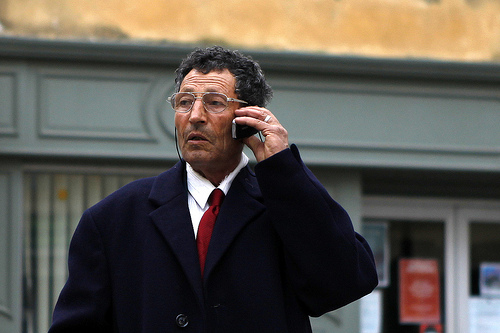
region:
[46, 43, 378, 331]
Man talking on his cell phone.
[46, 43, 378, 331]
Man wearing a dark red tie.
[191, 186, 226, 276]
Dark red tie.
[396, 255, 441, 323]
Red sign on a glass door.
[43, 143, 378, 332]
Navy blue wool coat.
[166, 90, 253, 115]
Eye glasses.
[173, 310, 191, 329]
Top button for a wool coat.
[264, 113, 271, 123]
Ring on man's finger.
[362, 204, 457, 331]
Glass door with signs on it.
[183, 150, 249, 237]
White dress shirt.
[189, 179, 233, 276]
Very bright red tir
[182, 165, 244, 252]
White collared t shirt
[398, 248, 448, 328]
White and red sign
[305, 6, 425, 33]
Light brown wood work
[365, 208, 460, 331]
Small glassdoor with signs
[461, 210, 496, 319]
Small glassdoor with signs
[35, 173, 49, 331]
White window valence in the window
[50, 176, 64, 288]
White window valence in the window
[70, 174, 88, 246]
White window valence in the window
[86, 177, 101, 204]
White window valence in the window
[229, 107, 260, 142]
His phone is black.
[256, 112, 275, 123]
He has a silver ring on.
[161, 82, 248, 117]
He is wearing glasses.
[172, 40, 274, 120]
He has dark hair.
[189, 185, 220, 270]
His tie is maroon.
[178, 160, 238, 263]
He has a white shirt on.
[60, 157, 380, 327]
His jacket is black.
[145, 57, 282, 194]
He is talking on the phone.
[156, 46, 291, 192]
He is holding a phone.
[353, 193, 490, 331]
The door is white.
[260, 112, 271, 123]
A ring on a man's finger.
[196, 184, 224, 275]
A red tie.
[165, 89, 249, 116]
A pair of glasses.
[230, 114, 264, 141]
A cellphone in a man's hand.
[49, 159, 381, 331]
A dark blue coat.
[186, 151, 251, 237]
A white shirt.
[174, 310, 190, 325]
A button on a coat.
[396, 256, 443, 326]
A red sign on a door.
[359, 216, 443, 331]
A glass door.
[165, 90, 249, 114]
A pair of glasses with silver frame.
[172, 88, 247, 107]
Silver rimmed glasses on man's face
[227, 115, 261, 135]
Cell phone in man's hand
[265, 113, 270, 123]
Ring on man's finger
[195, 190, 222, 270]
Red tie around man's neck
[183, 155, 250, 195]
Bright white shirt collar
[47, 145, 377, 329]
Dark blue coat on man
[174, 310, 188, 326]
Plastic button on man's coat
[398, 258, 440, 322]
Red sign in window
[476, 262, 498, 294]
White sign with picture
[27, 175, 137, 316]
Large venetian blinds in window